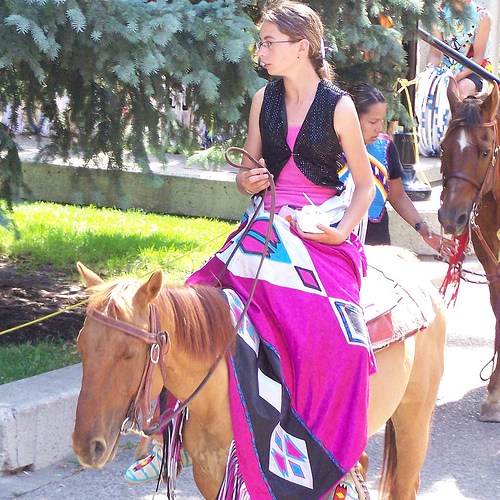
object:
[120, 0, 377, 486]
people